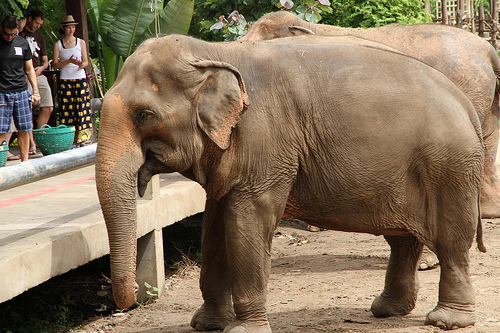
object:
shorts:
[26, 74, 54, 110]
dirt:
[0, 218, 499, 332]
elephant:
[94, 33, 488, 332]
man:
[0, 14, 42, 163]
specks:
[60, 96, 71, 104]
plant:
[84, 0, 192, 90]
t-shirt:
[0, 36, 33, 94]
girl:
[51, 14, 93, 147]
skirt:
[57, 79, 92, 145]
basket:
[32, 124, 77, 157]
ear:
[193, 61, 249, 151]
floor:
[0, 145, 195, 262]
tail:
[474, 138, 486, 255]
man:
[24, 10, 56, 155]